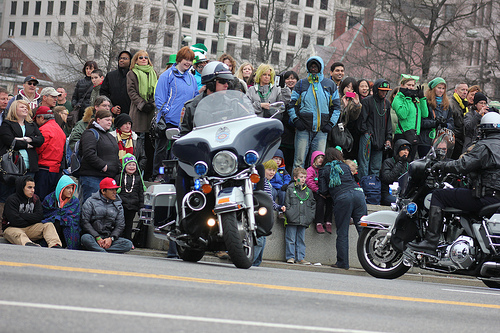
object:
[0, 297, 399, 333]
line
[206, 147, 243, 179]
headlight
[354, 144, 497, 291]
motorbike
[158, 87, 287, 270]
motorbike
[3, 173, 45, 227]
sweatshirt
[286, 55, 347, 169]
man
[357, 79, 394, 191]
man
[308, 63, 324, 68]
glasses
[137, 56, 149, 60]
glasses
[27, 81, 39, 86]
glasses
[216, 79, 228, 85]
glasses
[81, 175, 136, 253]
man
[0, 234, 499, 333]
road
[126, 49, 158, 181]
woman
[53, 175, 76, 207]
sweatshirt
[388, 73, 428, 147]
girl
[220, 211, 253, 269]
tire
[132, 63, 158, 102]
green scarf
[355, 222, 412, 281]
black wheel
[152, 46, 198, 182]
boy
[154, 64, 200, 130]
coat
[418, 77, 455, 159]
woman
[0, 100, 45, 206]
woman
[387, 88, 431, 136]
green coat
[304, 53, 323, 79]
hood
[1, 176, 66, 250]
man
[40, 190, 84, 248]
blanket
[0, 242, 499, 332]
pavement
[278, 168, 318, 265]
boy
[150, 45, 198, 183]
woman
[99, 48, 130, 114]
black coat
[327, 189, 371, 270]
pants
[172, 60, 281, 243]
man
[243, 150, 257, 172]
headlights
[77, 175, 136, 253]
man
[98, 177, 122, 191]
cap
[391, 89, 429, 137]
coat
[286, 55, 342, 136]
coat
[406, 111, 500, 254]
police officer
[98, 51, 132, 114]
man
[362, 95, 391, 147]
sweatshirt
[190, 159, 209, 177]
light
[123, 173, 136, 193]
necklace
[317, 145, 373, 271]
woman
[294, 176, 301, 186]
paint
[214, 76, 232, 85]
sunglasses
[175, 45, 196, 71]
head